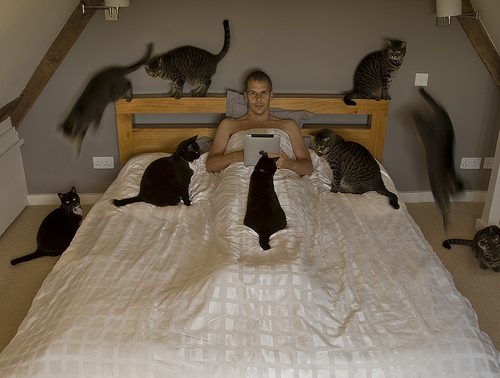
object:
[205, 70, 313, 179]
man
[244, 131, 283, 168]
ipad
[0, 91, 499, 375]
bed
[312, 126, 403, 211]
cats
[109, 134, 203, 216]
cat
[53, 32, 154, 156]
cat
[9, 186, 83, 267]
cat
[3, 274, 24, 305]
floor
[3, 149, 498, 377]
bedspread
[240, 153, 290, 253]
cat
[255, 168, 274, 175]
collar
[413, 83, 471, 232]
cat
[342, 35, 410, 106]
cat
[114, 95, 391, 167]
headboard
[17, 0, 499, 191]
wall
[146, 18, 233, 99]
cat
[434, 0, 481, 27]
lamp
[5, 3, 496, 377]
bedroom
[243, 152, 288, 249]
fur